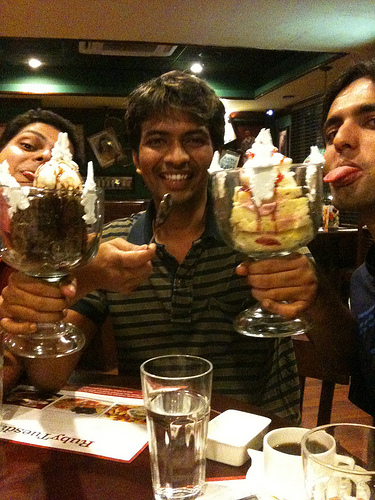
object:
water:
[147, 390, 205, 493]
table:
[5, 374, 375, 499]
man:
[0, 69, 357, 420]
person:
[322, 65, 375, 422]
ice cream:
[0, 134, 97, 260]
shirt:
[67, 196, 299, 423]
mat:
[2, 374, 375, 497]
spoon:
[149, 192, 173, 245]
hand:
[90, 239, 156, 292]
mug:
[262, 427, 355, 495]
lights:
[29, 59, 41, 68]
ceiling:
[2, 2, 375, 55]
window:
[293, 93, 371, 233]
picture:
[87, 127, 123, 168]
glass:
[139, 354, 214, 499]